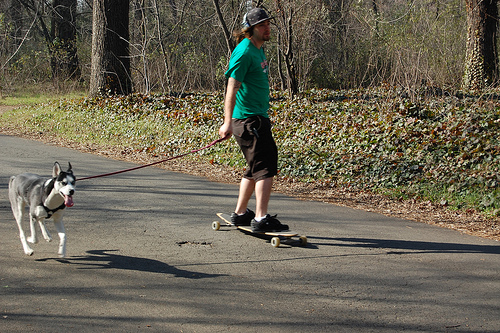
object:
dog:
[7, 160, 76, 256]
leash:
[73, 128, 232, 188]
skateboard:
[209, 208, 311, 249]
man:
[212, 2, 312, 251]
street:
[1, 129, 497, 331]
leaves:
[204, 155, 219, 167]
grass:
[96, 119, 127, 138]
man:
[217, 9, 290, 232]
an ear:
[52, 161, 62, 177]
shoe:
[249, 213, 290, 231]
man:
[221, 5, 292, 235]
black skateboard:
[211, 211, 307, 247]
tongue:
[64, 195, 74, 207]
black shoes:
[211, 212, 309, 247]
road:
[0, 132, 499, 331]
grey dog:
[8, 161, 78, 257]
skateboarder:
[208, 5, 310, 249]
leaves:
[332, 115, 496, 197]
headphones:
[240, 25, 256, 38]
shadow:
[36, 250, 233, 280]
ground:
[330, 222, 420, 314]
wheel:
[270, 237, 280, 247]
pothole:
[175, 238, 212, 247]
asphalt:
[3, 134, 496, 331]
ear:
[52, 161, 63, 178]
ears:
[52, 161, 73, 177]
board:
[211, 211, 309, 248]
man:
[198, 32, 314, 264]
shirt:
[219, 41, 276, 123]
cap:
[238, 8, 273, 31]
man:
[211, 6, 314, 249]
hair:
[233, 29, 249, 43]